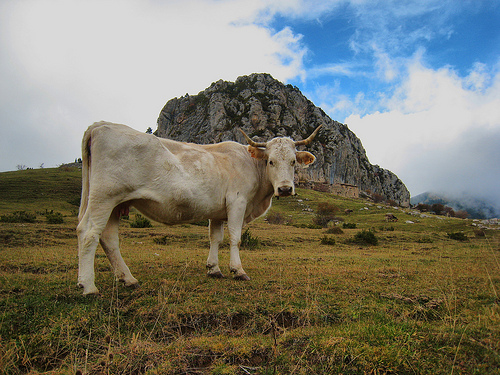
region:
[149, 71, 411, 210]
Rocky hill with scattered green plants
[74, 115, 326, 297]
White and tan bull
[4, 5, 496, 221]
Cloud filled sky with a little bit of blue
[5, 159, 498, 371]
Rocky field with green and brown grass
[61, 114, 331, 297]
Skinny bull with white face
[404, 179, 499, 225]
Hill covered in mist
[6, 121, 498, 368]
Cow standing alone in field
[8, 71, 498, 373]
Brown and green field with a rocky hill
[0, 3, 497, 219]
Hill set against a mostly cloudy sky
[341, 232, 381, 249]
Small dark green shrub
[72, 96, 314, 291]
a white cow that is walking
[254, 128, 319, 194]
the head of a white cow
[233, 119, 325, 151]
the horns of a white cow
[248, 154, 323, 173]
the ears of a white cow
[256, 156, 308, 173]
the eyes of a cow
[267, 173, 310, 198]
the nose of a cow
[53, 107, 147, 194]
the hind end of a cow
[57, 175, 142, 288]
the back legs of a cow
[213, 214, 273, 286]
the front legs of a cow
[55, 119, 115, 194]
the tail of a white cow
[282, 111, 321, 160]
This cow has some very large horns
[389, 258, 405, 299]
There is some green and brown grass here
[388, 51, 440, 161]
There are some clouds here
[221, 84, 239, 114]
There is a stone tower here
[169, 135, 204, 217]
There is light brown cow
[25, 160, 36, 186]
There is a small bush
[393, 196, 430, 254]
There is a small stone here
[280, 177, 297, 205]
This cow has a large nose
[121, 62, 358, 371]
Jackson Mingus took this photo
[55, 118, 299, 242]
brown cow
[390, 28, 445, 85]
white clouds in blue sky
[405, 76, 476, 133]
white clouds in blue sky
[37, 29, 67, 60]
white clouds in blue sky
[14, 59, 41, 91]
white clouds in blue sky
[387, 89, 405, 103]
white clouds in blue sky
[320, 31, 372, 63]
white clouds in blue sky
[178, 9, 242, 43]
white clouds in blue sky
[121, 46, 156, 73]
white clouds in blue sky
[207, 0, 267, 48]
white clouds in blue sky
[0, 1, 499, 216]
A blue sky with clouds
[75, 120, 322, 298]
A cow standing in front of a mountian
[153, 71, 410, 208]
A cliff or mountain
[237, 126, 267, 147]
Horn of a cow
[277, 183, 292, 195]
Nose of a cow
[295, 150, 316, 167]
Ear of a cow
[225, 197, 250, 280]
Front leg of a cow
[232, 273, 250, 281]
Hoof of a cow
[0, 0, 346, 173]
A large white cloud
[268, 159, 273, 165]
Eye of cow